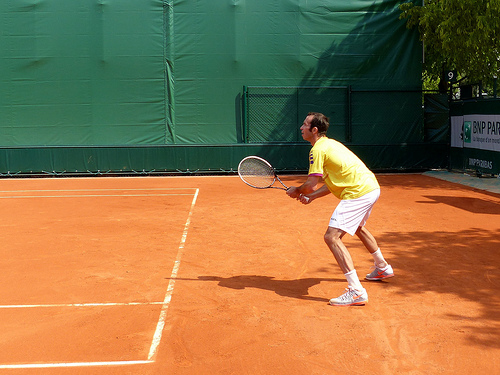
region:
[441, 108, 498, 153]
advertisement on a fence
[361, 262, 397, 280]
neon orange and white shoe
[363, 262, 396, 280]
shoe is multi colored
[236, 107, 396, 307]
man holding tennis racquet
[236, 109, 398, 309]
man playing tennis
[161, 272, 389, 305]
shadow of a man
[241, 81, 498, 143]
fence is painted green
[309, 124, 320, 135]
ear on mans head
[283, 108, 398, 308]
man in yellow shirt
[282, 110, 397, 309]
man in white shorts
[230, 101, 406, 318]
Man playing tennis.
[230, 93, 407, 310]
Tennis player waits for the ball.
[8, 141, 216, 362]
Orange floor of a tennis court.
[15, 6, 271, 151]
Green safety covering on a tennis court.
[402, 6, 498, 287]
Trees shading the back of the tennis court.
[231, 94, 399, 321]
Brown-haired man in a yellow shirt.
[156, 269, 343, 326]
A tennis-player's shadow.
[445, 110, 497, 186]
Sponsor signs hanging on the walls of the tennis court.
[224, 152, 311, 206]
Tennis racket held by a player.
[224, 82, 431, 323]
Tennis player waiting for the serve.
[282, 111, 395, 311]
crouching male tennis player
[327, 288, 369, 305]
white and orange Nike sneaker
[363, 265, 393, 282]
white and orange Nike sneaker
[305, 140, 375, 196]
yellow and black t-shirt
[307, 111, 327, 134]
short thinning brown hair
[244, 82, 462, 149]
green metal chain link fence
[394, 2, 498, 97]
green leafy tree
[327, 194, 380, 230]
white athletic shorts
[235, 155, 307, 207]
white and black tennis racket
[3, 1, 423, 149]
large green drape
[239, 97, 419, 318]
Man playing tennis on a tennis court.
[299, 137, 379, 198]
Man playing tennis wearing a yellow shirt.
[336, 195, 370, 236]
White shorts worn by man playing tennis.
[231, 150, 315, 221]
Tennis racket being held by man in yellow shirt.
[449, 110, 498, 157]
White banner sign on fence behind man playing tennis.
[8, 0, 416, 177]
Green tarp covering on side wall on tennis court.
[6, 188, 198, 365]
White boundary lines on tennis court.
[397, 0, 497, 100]
Trees in background of photo.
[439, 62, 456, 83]
Number 9 in background of photo.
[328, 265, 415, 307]
Sneakers worn by man playing tennis.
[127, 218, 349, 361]
shadow is cast on the ground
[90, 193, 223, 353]
the court lines are white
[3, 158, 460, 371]
this is a tennis court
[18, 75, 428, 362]
a tennis game is bieng played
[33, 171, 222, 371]
the weather is sunny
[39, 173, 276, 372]
the court is brown in color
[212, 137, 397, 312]
the player is holding a raquet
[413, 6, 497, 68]
the tree is green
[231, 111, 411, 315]
the player is male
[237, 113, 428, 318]
the player has white shorts